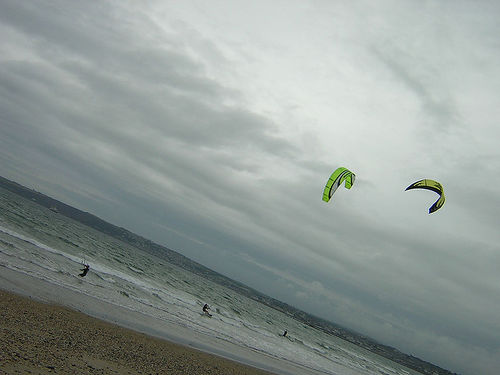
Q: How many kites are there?
A: Two.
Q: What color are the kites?
A: Green.